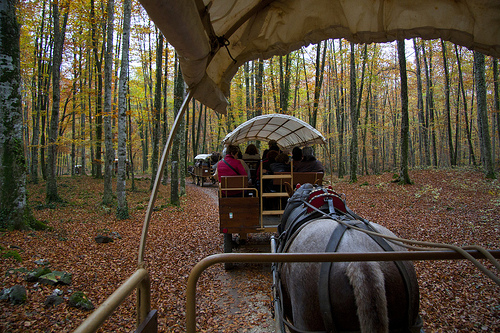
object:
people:
[218, 139, 324, 177]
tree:
[95, 23, 134, 220]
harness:
[277, 189, 359, 240]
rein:
[304, 200, 500, 283]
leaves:
[60, 21, 149, 286]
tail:
[343, 262, 393, 333]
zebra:
[273, 179, 420, 333]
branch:
[68, 39, 114, 180]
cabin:
[113, 158, 130, 179]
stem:
[377, 65, 399, 92]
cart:
[218, 113, 329, 273]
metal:
[186, 251, 258, 327]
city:
[324, 59, 500, 310]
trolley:
[189, 153, 221, 187]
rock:
[28, 267, 73, 285]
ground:
[395, 178, 475, 235]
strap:
[222, 159, 242, 176]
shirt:
[243, 150, 263, 168]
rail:
[74, 269, 157, 333]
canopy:
[222, 114, 325, 161]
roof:
[222, 112, 329, 149]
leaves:
[0, 171, 496, 330]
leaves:
[22, 0, 496, 167]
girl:
[217, 144, 247, 196]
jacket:
[217, 154, 247, 179]